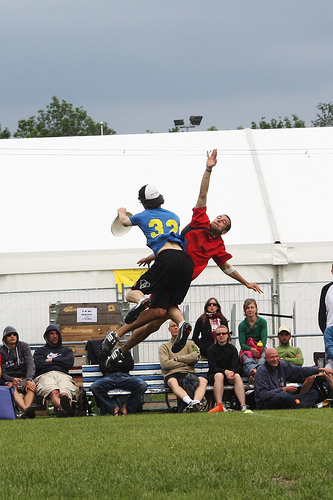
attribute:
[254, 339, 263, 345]
top — yellow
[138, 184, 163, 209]
hat — black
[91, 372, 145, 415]
jeans — blue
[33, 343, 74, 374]
shirt — black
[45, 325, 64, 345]
hood — black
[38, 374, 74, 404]
shorts — khaki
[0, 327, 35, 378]
sweatshirt — gray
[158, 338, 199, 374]
sweater — tan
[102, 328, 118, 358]
shoe — black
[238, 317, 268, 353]
shirt — green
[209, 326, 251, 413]
spectator — sitting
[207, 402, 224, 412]
cone — orange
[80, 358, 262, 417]
bench — blue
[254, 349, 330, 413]
man — sitting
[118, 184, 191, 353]
man — in the air, jumping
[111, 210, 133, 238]
frisbee — white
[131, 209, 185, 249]
shirt — blue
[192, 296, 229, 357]
woman — standing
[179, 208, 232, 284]
jersey — red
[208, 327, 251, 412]
woman — sitting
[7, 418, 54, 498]
grass — green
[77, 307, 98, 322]
sign — white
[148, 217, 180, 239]
number — in yellow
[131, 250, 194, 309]
shorts — black